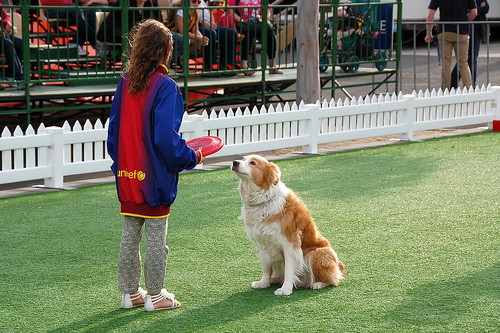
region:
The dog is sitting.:
[226, 136, 357, 318]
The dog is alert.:
[223, 146, 354, 302]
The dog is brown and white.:
[223, 146, 355, 308]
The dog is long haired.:
[224, 148, 356, 303]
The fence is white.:
[0, 73, 498, 193]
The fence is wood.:
[1, 78, 499, 188]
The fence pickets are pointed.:
[1, 76, 499, 188]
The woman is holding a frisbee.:
[101, 14, 231, 314]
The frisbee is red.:
[108, 12, 225, 173]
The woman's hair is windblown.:
[102, 11, 229, 168]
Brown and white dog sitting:
[225, 148, 350, 296]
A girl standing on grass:
[101, 18, 201, 319]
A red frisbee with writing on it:
[182, 128, 227, 178]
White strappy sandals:
[111, 282, 181, 319]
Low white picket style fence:
[6, 75, 491, 214]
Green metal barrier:
[10, 7, 406, 77]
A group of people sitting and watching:
[49, 3, 286, 84]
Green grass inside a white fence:
[21, 139, 487, 322]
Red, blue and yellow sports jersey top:
[91, 60, 201, 220]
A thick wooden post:
[286, 4, 331, 125]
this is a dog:
[218, 143, 362, 308]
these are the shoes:
[110, 276, 196, 324]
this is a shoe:
[133, 290, 186, 315]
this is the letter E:
[124, 169, 135, 181]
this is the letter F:
[127, 167, 141, 182]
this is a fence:
[1, 81, 496, 195]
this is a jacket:
[94, 54, 204, 228]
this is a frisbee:
[175, 129, 231, 171]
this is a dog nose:
[223, 156, 243, 175]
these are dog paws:
[243, 260, 351, 315]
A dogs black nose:
[230, 159, 240, 167]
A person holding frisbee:
[184, 134, 224, 162]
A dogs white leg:
[277, 244, 302, 296]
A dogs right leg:
[250, 242, 272, 291]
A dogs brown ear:
[262, 156, 284, 185]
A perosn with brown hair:
[110, 20, 172, 313]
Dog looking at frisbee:
[151, 86, 352, 302]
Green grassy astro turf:
[359, 186, 426, 246]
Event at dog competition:
[0, 2, 473, 326]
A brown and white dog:
[225, 149, 280, 192]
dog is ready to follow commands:
[228, 153, 349, 293]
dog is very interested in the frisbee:
[183, 134, 347, 288]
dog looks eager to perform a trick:
[183, 136, 350, 293]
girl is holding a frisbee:
[98, 19, 227, 312]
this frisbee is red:
[180, 132, 227, 159]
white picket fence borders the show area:
[1, 85, 498, 187]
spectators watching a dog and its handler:
[1, 1, 400, 78]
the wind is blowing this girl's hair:
[110, 16, 184, 100]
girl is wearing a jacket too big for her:
[102, 18, 204, 308]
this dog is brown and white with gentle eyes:
[229, 153, 349, 295]